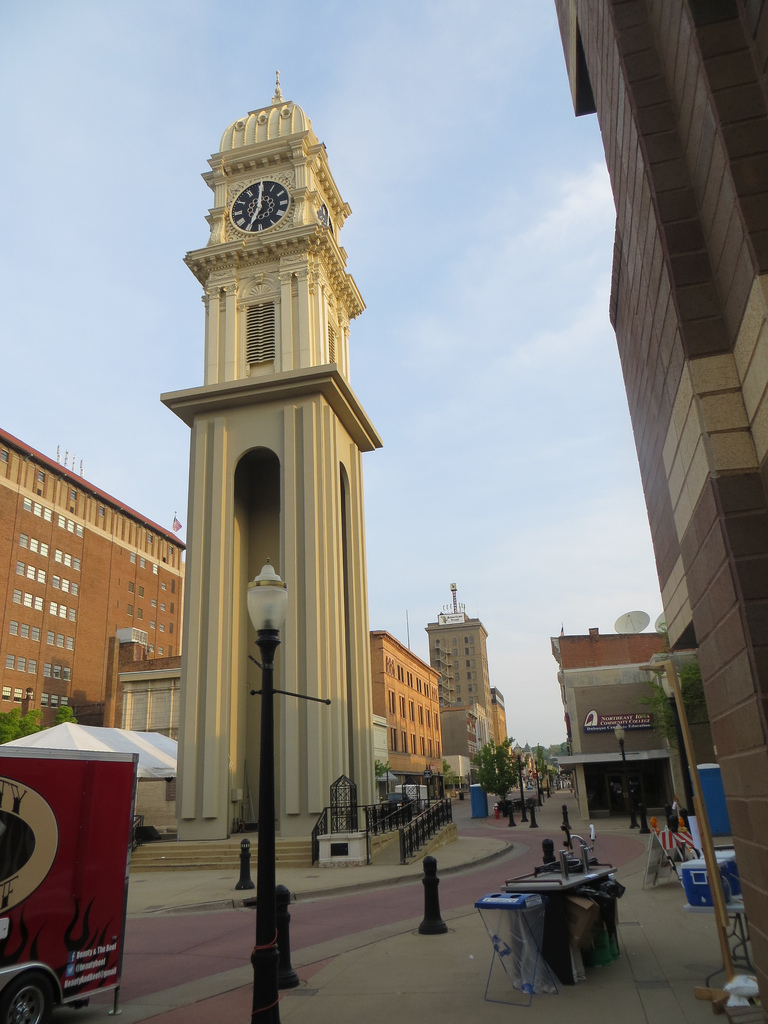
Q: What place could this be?
A: It is a city.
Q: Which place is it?
A: It is a city.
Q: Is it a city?
A: Yes, it is a city.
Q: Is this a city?
A: Yes, it is a city.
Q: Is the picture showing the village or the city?
A: It is showing the city.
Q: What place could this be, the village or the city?
A: It is the city.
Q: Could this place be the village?
A: No, it is the city.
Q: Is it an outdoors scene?
A: Yes, it is outdoors.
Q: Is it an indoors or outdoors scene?
A: It is outdoors.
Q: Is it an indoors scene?
A: No, it is outdoors.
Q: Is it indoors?
A: No, it is outdoors.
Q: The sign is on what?
A: The sign is on the building.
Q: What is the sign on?
A: The sign is on the building.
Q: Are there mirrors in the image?
A: No, there are no mirrors.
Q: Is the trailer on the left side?
A: Yes, the trailer is on the left of the image.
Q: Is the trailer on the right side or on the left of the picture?
A: The trailer is on the left of the image.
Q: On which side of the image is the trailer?
A: The trailer is on the left of the image.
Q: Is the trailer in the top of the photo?
A: No, the trailer is in the bottom of the image.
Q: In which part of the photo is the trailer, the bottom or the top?
A: The trailer is in the bottom of the image.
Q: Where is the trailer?
A: The trailer is on the sidewalk.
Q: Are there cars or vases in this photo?
A: No, there are no cars or vases.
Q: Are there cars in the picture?
A: No, there are no cars.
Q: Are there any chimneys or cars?
A: No, there are no cars or chimneys.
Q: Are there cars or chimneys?
A: No, there are no cars or chimneys.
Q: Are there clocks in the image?
A: Yes, there is a clock.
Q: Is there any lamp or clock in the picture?
A: Yes, there is a clock.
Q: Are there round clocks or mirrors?
A: Yes, there is a round clock.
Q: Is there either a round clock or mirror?
A: Yes, there is a round clock.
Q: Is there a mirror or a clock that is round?
A: Yes, the clock is round.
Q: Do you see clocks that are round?
A: Yes, there is a round clock.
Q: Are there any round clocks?
A: Yes, there is a round clock.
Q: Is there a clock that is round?
A: Yes, there is a clock that is round.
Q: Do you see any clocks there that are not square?
A: Yes, there is a round clock.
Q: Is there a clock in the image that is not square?
A: Yes, there is a round clock.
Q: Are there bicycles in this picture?
A: No, there are no bicycles.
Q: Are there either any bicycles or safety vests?
A: No, there are no bicycles or safety vests.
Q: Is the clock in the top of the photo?
A: Yes, the clock is in the top of the image.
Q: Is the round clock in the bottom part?
A: No, the clock is in the top of the image.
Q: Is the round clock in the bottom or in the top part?
A: The clock is in the top of the image.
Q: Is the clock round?
A: Yes, the clock is round.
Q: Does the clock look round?
A: Yes, the clock is round.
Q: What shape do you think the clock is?
A: The clock is round.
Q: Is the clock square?
A: No, the clock is round.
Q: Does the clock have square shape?
A: No, the clock is round.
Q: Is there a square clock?
A: No, there is a clock but it is round.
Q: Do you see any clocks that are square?
A: No, there is a clock but it is round.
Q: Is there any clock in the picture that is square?
A: No, there is a clock but it is round.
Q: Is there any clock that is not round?
A: No, there is a clock but it is round.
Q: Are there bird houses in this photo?
A: No, there are no bird houses.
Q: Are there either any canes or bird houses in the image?
A: No, there are no bird houses or canes.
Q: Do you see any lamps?
A: Yes, there is a lamp.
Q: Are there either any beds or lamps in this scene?
A: Yes, there is a lamp.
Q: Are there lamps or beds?
A: Yes, there is a lamp.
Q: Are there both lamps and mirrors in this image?
A: No, there is a lamp but no mirrors.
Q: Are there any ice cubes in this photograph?
A: No, there are no ice cubes.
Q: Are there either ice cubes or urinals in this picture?
A: No, there are no ice cubes or urinals.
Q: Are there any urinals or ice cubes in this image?
A: No, there are no ice cubes or urinals.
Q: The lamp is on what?
A: The lamp is on the pole.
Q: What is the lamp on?
A: The lamp is on the pole.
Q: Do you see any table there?
A: Yes, there is a table.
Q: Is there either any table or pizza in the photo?
A: Yes, there is a table.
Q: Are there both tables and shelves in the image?
A: No, there is a table but no shelves.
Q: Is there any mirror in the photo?
A: No, there are no mirrors.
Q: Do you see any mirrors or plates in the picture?
A: No, there are no mirrors or plates.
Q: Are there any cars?
A: No, there are no cars.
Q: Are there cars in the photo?
A: No, there are no cars.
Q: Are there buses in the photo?
A: No, there are no buses.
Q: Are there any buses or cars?
A: No, there are no buses or cars.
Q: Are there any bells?
A: No, there are no bells.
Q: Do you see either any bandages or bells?
A: No, there are no bells or bandages.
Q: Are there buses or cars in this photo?
A: No, there are no cars or buses.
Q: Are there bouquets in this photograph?
A: No, there are no bouquets.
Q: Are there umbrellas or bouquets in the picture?
A: No, there are no bouquets or umbrellas.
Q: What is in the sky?
A: The clouds are in the sky.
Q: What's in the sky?
A: The clouds are in the sky.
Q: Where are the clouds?
A: The clouds are in the sky.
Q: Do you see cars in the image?
A: No, there are no cars.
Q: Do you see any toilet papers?
A: No, there are no toilet papers.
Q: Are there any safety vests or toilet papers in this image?
A: No, there are no toilet papers or safety vests.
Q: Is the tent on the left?
A: Yes, the tent is on the left of the image.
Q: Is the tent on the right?
A: No, the tent is on the left of the image.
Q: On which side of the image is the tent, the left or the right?
A: The tent is on the left of the image.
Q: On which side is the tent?
A: The tent is on the left of the image.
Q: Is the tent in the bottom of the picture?
A: Yes, the tent is in the bottom of the image.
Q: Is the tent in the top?
A: No, the tent is in the bottom of the image.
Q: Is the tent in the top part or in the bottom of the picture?
A: The tent is in the bottom of the image.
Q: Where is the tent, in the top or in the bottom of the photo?
A: The tent is in the bottom of the image.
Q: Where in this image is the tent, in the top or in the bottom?
A: The tent is in the bottom of the image.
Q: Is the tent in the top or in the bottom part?
A: The tent is in the bottom of the image.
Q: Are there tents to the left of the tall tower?
A: Yes, there is a tent to the left of the tower.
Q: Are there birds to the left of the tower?
A: No, there is a tent to the left of the tower.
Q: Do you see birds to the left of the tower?
A: No, there is a tent to the left of the tower.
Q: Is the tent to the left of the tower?
A: Yes, the tent is to the left of the tower.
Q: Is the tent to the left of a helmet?
A: No, the tent is to the left of the tower.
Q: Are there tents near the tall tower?
A: Yes, there is a tent near the tower.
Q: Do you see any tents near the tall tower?
A: Yes, there is a tent near the tower.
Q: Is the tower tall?
A: Yes, the tower is tall.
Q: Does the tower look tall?
A: Yes, the tower is tall.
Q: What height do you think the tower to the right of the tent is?
A: The tower is tall.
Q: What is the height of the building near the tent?
A: The tower is tall.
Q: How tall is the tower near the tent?
A: The tower is tall.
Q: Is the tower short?
A: No, the tower is tall.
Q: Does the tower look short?
A: No, the tower is tall.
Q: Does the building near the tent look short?
A: No, the tower is tall.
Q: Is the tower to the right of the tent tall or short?
A: The tower is tall.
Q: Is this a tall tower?
A: Yes, this is a tall tower.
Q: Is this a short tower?
A: No, this is a tall tower.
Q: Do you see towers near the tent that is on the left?
A: Yes, there is a tower near the tent.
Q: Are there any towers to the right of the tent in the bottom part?
A: Yes, there is a tower to the right of the tent.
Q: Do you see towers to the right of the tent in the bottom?
A: Yes, there is a tower to the right of the tent.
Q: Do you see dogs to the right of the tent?
A: No, there is a tower to the right of the tent.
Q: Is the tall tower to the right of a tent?
A: Yes, the tower is to the right of a tent.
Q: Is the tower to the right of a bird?
A: No, the tower is to the right of a tent.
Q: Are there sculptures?
A: No, there are no sculptures.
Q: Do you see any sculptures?
A: No, there are no sculptures.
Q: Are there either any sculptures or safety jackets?
A: No, there are no sculptures or safety jackets.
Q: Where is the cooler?
A: The cooler is on the side walk.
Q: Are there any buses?
A: No, there are no buses.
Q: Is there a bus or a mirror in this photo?
A: No, there are no buses or mirrors.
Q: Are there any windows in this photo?
A: Yes, there are windows.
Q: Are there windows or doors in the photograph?
A: Yes, there are windows.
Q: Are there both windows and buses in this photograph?
A: No, there are windows but no buses.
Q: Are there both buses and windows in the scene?
A: No, there are windows but no buses.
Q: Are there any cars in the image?
A: No, there are no cars.